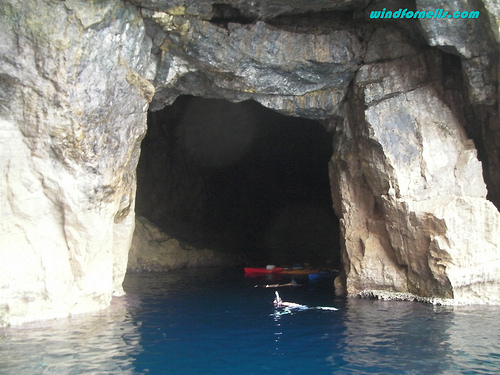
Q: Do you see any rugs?
A: No, there are no rugs.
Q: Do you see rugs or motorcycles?
A: No, there are no rugs or motorcycles.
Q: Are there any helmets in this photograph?
A: No, there are no helmets.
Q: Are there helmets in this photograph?
A: No, there are no helmets.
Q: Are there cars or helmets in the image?
A: No, there are no helmets or cars.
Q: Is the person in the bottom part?
A: Yes, the person is in the bottom of the image.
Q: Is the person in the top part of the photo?
A: No, the person is in the bottom of the image.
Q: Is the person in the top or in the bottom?
A: The person is in the bottom of the image.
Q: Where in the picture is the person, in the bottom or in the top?
A: The person is in the bottom of the image.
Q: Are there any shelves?
A: No, there are no shelves.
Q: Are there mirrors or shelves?
A: No, there are no shelves or mirrors.